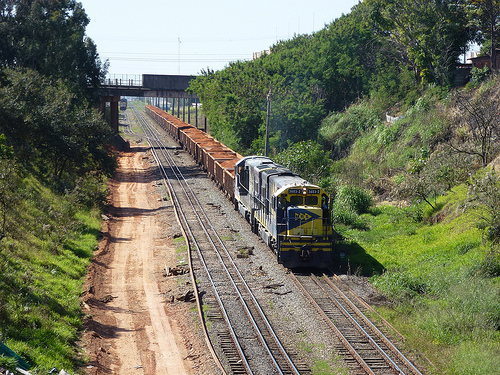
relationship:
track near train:
[126, 102, 301, 373] [233, 152, 338, 270]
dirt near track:
[78, 135, 208, 374] [126, 102, 301, 373]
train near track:
[233, 152, 338, 270] [126, 102, 301, 373]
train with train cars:
[233, 152, 338, 270] [144, 100, 248, 198]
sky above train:
[1, 1, 362, 105] [233, 152, 338, 270]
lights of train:
[300, 186, 308, 199] [233, 152, 338, 270]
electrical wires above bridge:
[99, 44, 249, 70] [92, 75, 207, 135]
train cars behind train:
[144, 100, 248, 198] [233, 152, 338, 270]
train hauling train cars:
[233, 152, 338, 270] [144, 100, 248, 198]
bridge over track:
[92, 75, 207, 135] [126, 102, 301, 373]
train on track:
[233, 152, 338, 270] [299, 274, 402, 373]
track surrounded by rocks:
[126, 102, 301, 373] [129, 122, 219, 369]